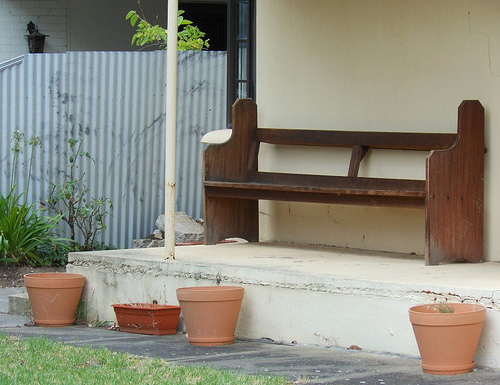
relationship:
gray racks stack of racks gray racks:
[138, 199, 200, 249] [142, 197, 196, 250]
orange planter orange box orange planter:
[107, 299, 176, 346] [107, 295, 182, 338]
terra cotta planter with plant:
[414, 298, 486, 369] [54, 178, 107, 270]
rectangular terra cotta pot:
[114, 297, 164, 345] [98, 277, 174, 385]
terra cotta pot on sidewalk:
[20, 270, 85, 329] [97, 336, 358, 354]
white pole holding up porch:
[153, 3, 187, 258] [94, 264, 490, 304]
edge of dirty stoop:
[72, 253, 151, 286] [72, 261, 131, 349]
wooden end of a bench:
[412, 151, 469, 268] [422, 163, 448, 244]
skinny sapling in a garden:
[5, 125, 49, 197] [56, 164, 98, 230]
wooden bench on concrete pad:
[188, 98, 487, 263] [267, 235, 394, 327]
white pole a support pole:
[153, 3, 187, 258] [151, 86, 200, 234]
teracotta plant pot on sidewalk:
[102, 293, 189, 385] [261, 318, 349, 385]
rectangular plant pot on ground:
[110, 297, 182, 334] [143, 338, 270, 385]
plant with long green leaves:
[49, 162, 109, 272] [28, 149, 97, 229]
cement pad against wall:
[65, 221, 500, 325] [264, 318, 309, 383]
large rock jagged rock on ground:
[147, 199, 200, 249] [27, 237, 160, 329]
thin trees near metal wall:
[8, 125, 41, 208] [87, 102, 193, 213]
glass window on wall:
[233, 3, 254, 115] [250, 50, 341, 113]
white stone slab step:
[4, 281, 31, 319] [264, 258, 346, 328]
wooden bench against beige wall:
[188, 98, 487, 263] [250, 2, 500, 257]